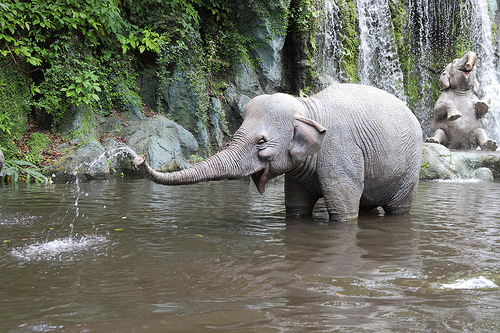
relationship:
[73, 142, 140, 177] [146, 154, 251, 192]
water sprouting from trunk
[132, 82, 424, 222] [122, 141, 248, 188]
elephant has a trunk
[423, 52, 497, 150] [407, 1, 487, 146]
elephant under waterfall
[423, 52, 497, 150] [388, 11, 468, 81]
elephant under waterfall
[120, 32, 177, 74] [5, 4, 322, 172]
plants growing on side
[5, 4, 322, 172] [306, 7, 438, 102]
side of waterfall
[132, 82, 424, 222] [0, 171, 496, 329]
elephant in water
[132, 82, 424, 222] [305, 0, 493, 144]
elephant playing in waterfall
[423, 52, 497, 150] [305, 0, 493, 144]
elephant playing in waterfall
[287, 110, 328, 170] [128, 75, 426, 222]
ear of elephant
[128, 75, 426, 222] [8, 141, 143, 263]
elephant shooting water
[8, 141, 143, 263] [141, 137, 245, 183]
water out of trunk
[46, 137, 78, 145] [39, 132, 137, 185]
leaves on rock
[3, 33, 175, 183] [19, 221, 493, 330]
large rocks in water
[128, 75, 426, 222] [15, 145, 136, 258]
elephant squirting water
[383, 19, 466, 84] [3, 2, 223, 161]
grass growing on side of cliff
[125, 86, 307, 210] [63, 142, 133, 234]
elephant water spraying water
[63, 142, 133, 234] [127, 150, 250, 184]
water out of trunk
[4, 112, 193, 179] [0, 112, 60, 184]
riverbank with foilage